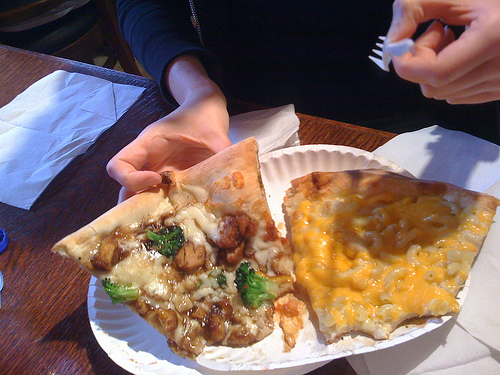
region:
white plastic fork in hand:
[355, 18, 429, 90]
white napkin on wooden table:
[0, 50, 147, 216]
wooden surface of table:
[15, 250, 56, 319]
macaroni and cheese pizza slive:
[280, 161, 497, 331]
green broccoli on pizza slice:
[230, 262, 278, 309]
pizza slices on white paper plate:
[25, 99, 479, 359]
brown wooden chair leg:
[95, 7, 144, 87]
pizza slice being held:
[10, 76, 297, 356]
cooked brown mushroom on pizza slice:
[173, 239, 212, 274]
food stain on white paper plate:
[110, 347, 172, 372]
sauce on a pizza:
[318, 188, 373, 226]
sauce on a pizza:
[305, 214, 340, 258]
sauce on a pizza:
[309, 260, 334, 307]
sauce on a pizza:
[341, 270, 363, 301]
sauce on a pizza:
[356, 284, 383, 314]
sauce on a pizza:
[373, 278, 403, 312]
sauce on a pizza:
[388, 244, 412, 271]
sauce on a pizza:
[373, 218, 401, 245]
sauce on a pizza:
[407, 215, 437, 241]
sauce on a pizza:
[410, 267, 446, 305]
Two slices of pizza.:
[11, 13, 485, 355]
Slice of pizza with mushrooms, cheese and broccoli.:
[72, 139, 297, 354]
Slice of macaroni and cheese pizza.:
[287, 165, 494, 349]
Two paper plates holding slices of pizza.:
[56, 123, 478, 373]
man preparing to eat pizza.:
[84, 9, 496, 371]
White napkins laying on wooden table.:
[4, 65, 490, 231]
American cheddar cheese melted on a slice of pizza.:
[290, 164, 490, 361]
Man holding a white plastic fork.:
[348, 17, 436, 87]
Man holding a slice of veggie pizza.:
[104, 82, 242, 229]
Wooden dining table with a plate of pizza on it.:
[10, 49, 439, 363]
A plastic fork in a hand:
[365, 30, 416, 72]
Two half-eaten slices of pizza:
[58, 150, 492, 346]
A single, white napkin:
[6, 70, 146, 211]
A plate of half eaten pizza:
[76, 140, 461, 365]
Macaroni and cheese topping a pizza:
[303, 212, 445, 295]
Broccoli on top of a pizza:
[143, 224, 184, 251]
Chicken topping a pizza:
[93, 239, 124, 266]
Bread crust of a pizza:
[56, 133, 259, 260]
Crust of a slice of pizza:
[283, 168, 498, 217]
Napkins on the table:
[378, 125, 499, 180]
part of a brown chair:
[0, 5, 134, 72]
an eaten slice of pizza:
[277, 165, 495, 337]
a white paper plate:
[196, 151, 443, 373]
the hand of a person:
[102, 103, 234, 195]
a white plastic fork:
[364, 25, 425, 69]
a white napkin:
[0, 68, 147, 215]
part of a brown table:
[0, 45, 73, 102]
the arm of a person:
[107, 4, 213, 93]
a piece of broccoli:
[232, 263, 275, 306]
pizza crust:
[46, 138, 258, 260]